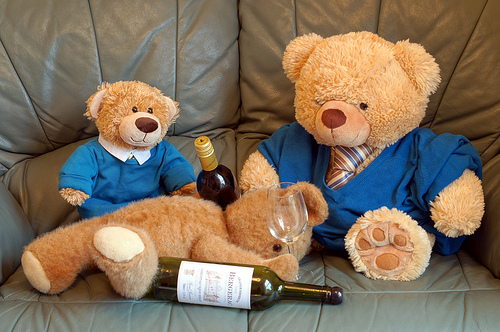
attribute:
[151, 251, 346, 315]
bottle — green, wine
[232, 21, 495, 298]
bear — teddy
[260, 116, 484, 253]
shirt — blue, blue and white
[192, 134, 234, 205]
bottle — cognac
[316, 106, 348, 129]
nose — brown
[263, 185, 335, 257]
wine glass — empty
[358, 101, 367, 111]
eye — black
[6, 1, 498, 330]
couch — gray, leather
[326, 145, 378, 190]
tie — colorful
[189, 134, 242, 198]
bottle — green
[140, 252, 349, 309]
bottle — wine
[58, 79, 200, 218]
brown bear — small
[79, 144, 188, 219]
tee shirt — blue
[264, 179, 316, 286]
glass — wine, clear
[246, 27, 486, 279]
teddy bear — large, brown, plush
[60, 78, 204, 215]
teddy bear — brown, small, plush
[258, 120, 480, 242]
shirt — blue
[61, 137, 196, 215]
shirt — blue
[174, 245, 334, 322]
bottle — empty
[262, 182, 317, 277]
glass — clear, empty, drinking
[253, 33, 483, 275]
bear — brown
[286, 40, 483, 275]
teddy bear — large, brown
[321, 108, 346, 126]
nose — brown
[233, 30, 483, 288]
bear — large, bigger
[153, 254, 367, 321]
bottle — green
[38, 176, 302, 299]
bear — intoxicated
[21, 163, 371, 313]
bear — intoxicated